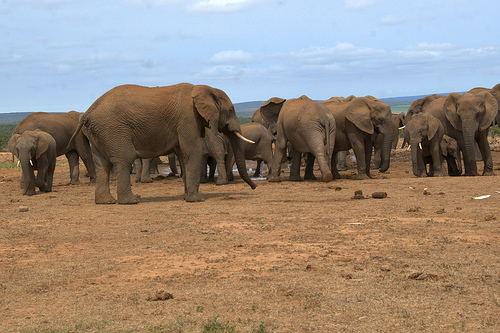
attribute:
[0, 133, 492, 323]
grass — brown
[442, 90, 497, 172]
elephants — several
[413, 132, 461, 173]
elephants — several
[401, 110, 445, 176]
elephants — several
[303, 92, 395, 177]
elephants — several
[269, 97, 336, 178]
elephants — several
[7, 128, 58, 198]
elephant — many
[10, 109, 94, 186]
elephant — many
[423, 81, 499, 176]
elephant — many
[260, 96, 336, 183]
elephant — many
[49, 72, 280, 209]
elephant — baby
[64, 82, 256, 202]
elephant — many, grey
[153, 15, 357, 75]
sky — partly cloudy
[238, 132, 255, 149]
tusk — elephant, many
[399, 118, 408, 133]
tusk — elephant, many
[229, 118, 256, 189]
trunk — long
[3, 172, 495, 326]
soil — orange, sandy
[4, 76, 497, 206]
elephants — gray, brown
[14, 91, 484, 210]
elephants — standing